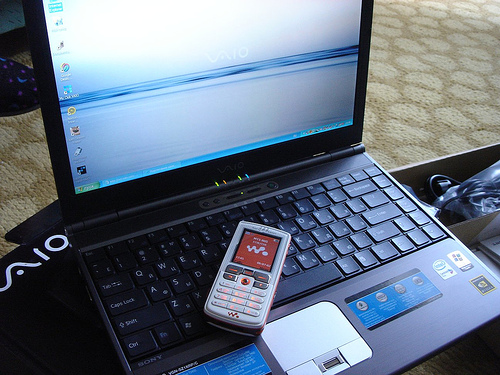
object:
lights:
[215, 174, 250, 187]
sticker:
[344, 268, 443, 332]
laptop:
[319, 225, 467, 366]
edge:
[352, 1, 374, 142]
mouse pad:
[260, 301, 373, 374]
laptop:
[38, 8, 479, 360]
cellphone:
[203, 220, 291, 337]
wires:
[424, 174, 500, 217]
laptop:
[62, 21, 404, 315]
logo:
[246, 245, 268, 256]